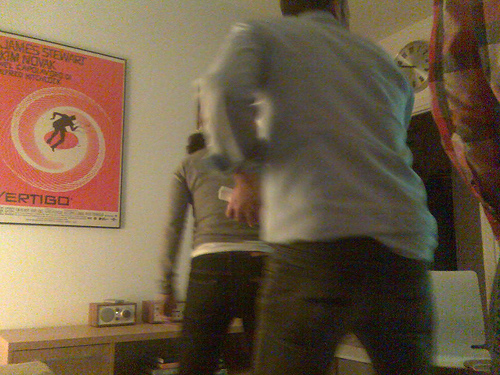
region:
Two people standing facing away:
[151, 3, 444, 372]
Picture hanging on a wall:
[1, 23, 138, 242]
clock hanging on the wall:
[385, 31, 442, 103]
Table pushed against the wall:
[0, 301, 281, 373]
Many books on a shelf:
[137, 350, 230, 372]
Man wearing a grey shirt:
[201, 15, 444, 255]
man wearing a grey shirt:
[155, 150, 260, 312]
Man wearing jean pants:
[178, 249, 260, 372]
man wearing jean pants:
[251, 238, 446, 365]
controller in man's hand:
[210, 177, 267, 227]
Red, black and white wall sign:
[1, 28, 128, 233]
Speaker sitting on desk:
[87, 298, 137, 330]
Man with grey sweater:
[157, 128, 270, 374]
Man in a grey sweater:
[200, 1, 442, 374]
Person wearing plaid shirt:
[427, 1, 498, 374]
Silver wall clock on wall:
[389, 38, 436, 95]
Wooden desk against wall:
[0, 312, 251, 374]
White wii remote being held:
[215, 176, 268, 226]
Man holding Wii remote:
[194, 1, 440, 371]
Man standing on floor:
[155, 131, 276, 374]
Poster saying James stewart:
[0, 30, 106, 155]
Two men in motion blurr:
[132, 29, 444, 330]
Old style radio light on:
[82, 283, 144, 336]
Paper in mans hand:
[206, 150, 276, 253]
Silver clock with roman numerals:
[375, 25, 447, 105]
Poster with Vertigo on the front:
[0, 22, 162, 247]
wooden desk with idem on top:
[0, 321, 174, 373]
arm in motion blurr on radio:
[141, 251, 191, 338]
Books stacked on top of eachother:
[137, 335, 192, 373]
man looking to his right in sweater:
[265, 3, 357, 54]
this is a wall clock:
[407, 46, 428, 68]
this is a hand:
[210, 71, 259, 221]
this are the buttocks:
[252, 250, 429, 325]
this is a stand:
[8, 331, 112, 360]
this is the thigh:
[186, 311, 218, 368]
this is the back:
[278, 29, 395, 229]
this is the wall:
[106, 20, 184, 50]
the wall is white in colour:
[110, 15, 211, 30]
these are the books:
[150, 345, 167, 371]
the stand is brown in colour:
[6, 337, 109, 359]